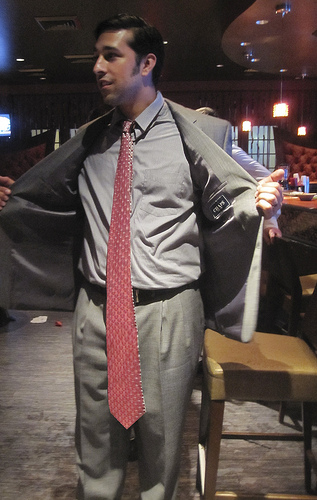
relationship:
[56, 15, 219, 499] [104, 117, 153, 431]
man wears necktie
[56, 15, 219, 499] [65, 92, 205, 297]
man wears shirt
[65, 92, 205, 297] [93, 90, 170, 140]
shirt has collar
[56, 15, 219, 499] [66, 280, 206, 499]
man wears pants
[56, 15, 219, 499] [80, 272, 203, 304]
man wears belt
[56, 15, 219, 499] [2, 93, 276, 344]
man wears jacket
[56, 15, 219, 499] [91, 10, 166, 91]
man has hair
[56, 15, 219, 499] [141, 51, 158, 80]
man has ear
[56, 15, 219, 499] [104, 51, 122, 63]
man has eye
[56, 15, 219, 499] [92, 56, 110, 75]
man has nose